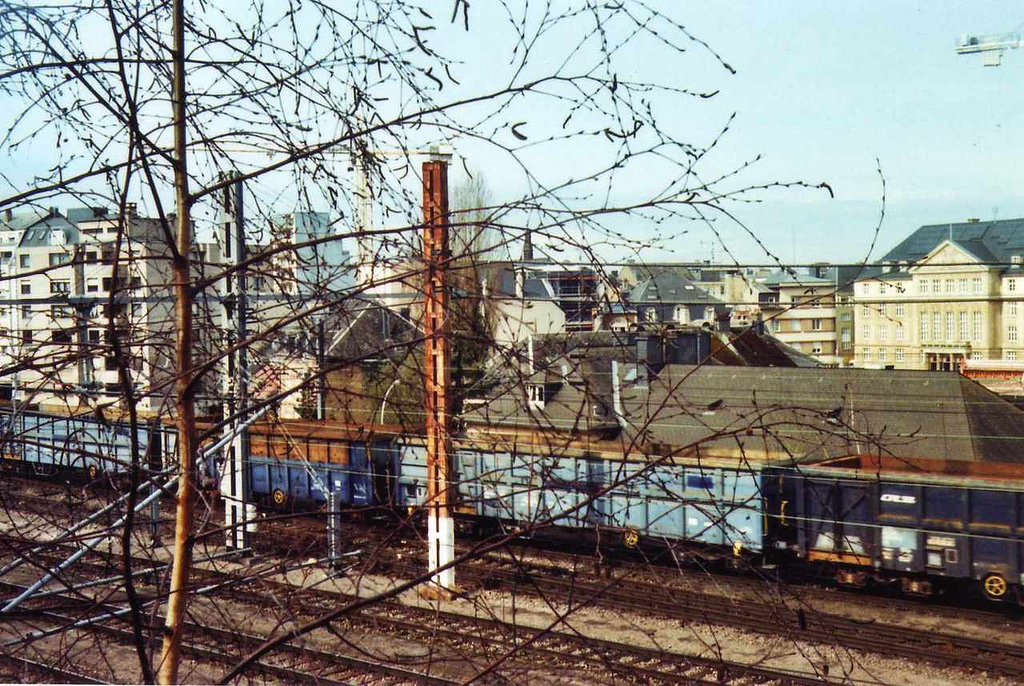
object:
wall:
[855, 279, 1024, 369]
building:
[854, 218, 1023, 368]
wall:
[3, 243, 146, 412]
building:
[2, 204, 224, 419]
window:
[49, 252, 74, 266]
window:
[915, 278, 929, 296]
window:
[893, 323, 906, 342]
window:
[47, 277, 74, 297]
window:
[19, 253, 33, 271]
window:
[20, 302, 37, 323]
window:
[862, 283, 871, 303]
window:
[20, 326, 34, 350]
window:
[860, 324, 874, 338]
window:
[810, 318, 824, 332]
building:
[754, 264, 855, 366]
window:
[789, 296, 806, 311]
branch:
[195, 303, 600, 445]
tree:
[3, 2, 821, 685]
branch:
[187, 3, 742, 205]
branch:
[2, 6, 185, 165]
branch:
[194, 319, 671, 442]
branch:
[214, 393, 926, 684]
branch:
[189, 453, 709, 552]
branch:
[91, 1, 189, 272]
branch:
[109, 2, 164, 684]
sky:
[3, 4, 1021, 286]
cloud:
[68, 9, 878, 272]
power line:
[2, 258, 1024, 269]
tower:
[411, 144, 461, 594]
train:
[0, 402, 1020, 604]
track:
[6, 459, 1021, 676]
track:
[2, 534, 843, 685]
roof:
[855, 216, 1022, 281]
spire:
[521, 220, 534, 260]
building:
[488, 259, 614, 333]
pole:
[213, 171, 248, 556]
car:
[792, 455, 1020, 589]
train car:
[161, 416, 399, 516]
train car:
[397, 422, 797, 580]